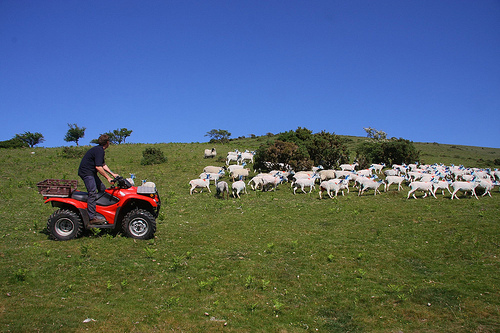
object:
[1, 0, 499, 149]
sky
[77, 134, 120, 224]
man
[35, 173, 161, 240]
wheeler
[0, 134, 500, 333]
grass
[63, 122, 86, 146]
tree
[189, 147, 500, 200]
cattle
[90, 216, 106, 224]
boot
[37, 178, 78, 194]
basket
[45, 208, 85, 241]
wheel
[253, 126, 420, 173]
bush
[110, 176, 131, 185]
steering wheel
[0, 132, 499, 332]
hill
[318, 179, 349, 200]
sheep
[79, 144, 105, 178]
shirt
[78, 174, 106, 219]
jeans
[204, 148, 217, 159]
sheep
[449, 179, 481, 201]
sheep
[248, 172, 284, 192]
sheep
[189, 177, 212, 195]
sheep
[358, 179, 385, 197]
sheep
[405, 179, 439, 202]
sheep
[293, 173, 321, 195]
sheep